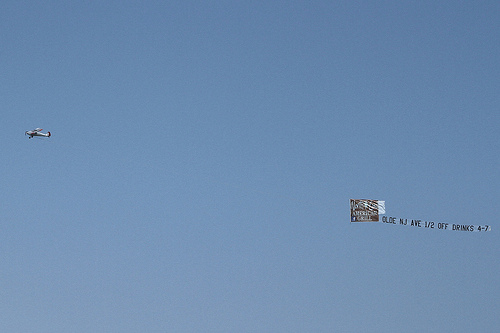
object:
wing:
[35, 128, 43, 132]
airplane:
[25, 127, 51, 139]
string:
[379, 215, 490, 232]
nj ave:
[400, 218, 422, 228]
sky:
[2, 2, 499, 332]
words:
[382, 216, 490, 232]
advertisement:
[350, 198, 491, 233]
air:
[0, 0, 500, 333]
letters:
[382, 215, 396, 224]